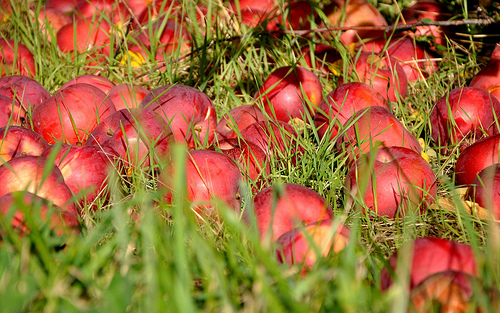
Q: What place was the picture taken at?
A: It was taken at the field.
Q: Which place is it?
A: It is a field.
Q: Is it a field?
A: Yes, it is a field.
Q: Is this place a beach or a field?
A: It is a field.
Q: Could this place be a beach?
A: No, it is a field.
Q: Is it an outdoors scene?
A: Yes, it is outdoors.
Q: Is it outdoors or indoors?
A: It is outdoors.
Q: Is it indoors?
A: No, it is outdoors.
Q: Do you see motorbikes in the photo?
A: No, there are no motorbikes.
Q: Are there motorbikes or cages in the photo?
A: No, there are no motorbikes or cages.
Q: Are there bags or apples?
A: Yes, there is an apple.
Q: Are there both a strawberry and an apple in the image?
A: No, there is an apple but no strawberries.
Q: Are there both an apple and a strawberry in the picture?
A: No, there is an apple but no strawberries.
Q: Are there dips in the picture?
A: No, there are no dips.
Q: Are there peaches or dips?
A: No, there are no dips or peaches.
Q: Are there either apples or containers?
A: Yes, there is an apple.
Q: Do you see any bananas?
A: No, there are no bananas.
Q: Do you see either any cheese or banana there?
A: No, there are no bananas or cheese.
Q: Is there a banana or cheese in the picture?
A: No, there are no bananas or cheese.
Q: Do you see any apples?
A: Yes, there is an apple.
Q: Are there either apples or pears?
A: Yes, there is an apple.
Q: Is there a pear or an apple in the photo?
A: Yes, there is an apple.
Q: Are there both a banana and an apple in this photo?
A: No, there is an apple but no bananas.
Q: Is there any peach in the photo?
A: No, there are no peaches.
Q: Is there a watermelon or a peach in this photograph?
A: No, there are no peaches or watermelons.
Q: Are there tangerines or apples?
A: Yes, there is an apple.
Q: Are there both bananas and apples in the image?
A: No, there is an apple but no bananas.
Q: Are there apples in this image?
A: Yes, there is an apple.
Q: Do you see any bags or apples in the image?
A: Yes, there is an apple.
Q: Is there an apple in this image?
A: Yes, there is an apple.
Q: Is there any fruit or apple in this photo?
A: Yes, there is an apple.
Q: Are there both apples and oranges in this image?
A: No, there is an apple but no oranges.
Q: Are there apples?
A: Yes, there is an apple.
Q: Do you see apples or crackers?
A: Yes, there is an apple.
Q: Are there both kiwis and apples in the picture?
A: No, there is an apple but no kiwis.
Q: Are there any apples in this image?
A: Yes, there is an apple.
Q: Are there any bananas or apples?
A: Yes, there is an apple.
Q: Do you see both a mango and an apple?
A: No, there is an apple but no mangoes.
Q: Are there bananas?
A: No, there are no bananas.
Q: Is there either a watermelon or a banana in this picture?
A: No, there are no bananas or watermelons.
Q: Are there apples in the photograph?
A: Yes, there is an apple.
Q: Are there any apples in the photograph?
A: Yes, there is an apple.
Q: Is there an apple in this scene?
A: Yes, there is an apple.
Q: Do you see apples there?
A: Yes, there is an apple.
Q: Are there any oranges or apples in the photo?
A: Yes, there is an apple.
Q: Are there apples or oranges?
A: Yes, there is an apple.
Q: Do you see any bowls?
A: No, there are no bowls.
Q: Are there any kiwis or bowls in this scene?
A: No, there are no bowls or kiwis.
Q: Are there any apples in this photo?
A: Yes, there is an apple.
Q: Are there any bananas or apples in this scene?
A: Yes, there is an apple.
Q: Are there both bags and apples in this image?
A: No, there is an apple but no bags.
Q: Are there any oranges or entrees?
A: No, there are no oranges or entrees.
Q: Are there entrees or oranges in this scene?
A: No, there are no oranges or entrees.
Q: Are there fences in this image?
A: No, there are no fences.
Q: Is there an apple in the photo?
A: Yes, there is an apple.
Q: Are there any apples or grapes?
A: Yes, there is an apple.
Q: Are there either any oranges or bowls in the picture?
A: No, there are no oranges or bowls.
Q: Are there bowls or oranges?
A: No, there are no oranges or bowls.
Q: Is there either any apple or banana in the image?
A: Yes, there is an apple.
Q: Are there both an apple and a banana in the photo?
A: No, there is an apple but no bananas.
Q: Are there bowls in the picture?
A: No, there are no bowls.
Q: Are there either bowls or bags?
A: No, there are no bowls or bags.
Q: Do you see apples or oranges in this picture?
A: Yes, there are apples.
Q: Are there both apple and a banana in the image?
A: No, there are apples but no bananas.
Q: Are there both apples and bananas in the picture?
A: No, there are apples but no bananas.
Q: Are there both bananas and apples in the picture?
A: No, there are apples but no bananas.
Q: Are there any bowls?
A: No, there are no bowls.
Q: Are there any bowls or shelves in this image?
A: No, there are no bowls or shelves.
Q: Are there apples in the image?
A: Yes, there is an apple.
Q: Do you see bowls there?
A: No, there are no bowls.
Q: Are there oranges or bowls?
A: No, there are no bowls or oranges.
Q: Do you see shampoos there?
A: No, there are no shampoos.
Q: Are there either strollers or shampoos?
A: No, there are no shampoos or strollers.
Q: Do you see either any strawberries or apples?
A: Yes, there is an apple.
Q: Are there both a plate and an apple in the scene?
A: No, there is an apple but no plates.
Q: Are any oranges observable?
A: No, there are no oranges.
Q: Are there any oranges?
A: No, there are no oranges.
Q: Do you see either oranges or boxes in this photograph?
A: No, there are no oranges or boxes.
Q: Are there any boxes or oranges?
A: No, there are no oranges or boxes.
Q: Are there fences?
A: No, there are no fences.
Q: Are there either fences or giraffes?
A: No, there are no fences or giraffes.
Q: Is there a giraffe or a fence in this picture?
A: No, there are no fences or giraffes.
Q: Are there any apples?
A: Yes, there is an apple.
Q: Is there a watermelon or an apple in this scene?
A: Yes, there is an apple.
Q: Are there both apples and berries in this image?
A: No, there is an apple but no berries.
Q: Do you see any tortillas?
A: No, there are no tortillas.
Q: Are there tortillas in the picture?
A: No, there are no tortillas.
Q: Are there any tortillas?
A: No, there are no tortillas.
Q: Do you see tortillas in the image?
A: No, there are no tortillas.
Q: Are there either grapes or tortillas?
A: No, there are no tortillas or grapes.